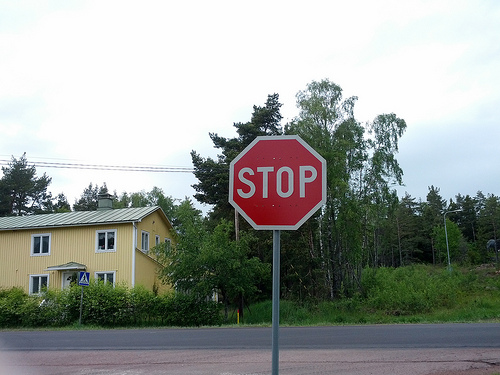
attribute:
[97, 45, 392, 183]
clouds — white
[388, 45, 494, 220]
sky — blue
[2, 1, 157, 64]
clouds — white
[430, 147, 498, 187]
sky — blue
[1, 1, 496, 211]
clouds — white 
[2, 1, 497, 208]
sky — blue 